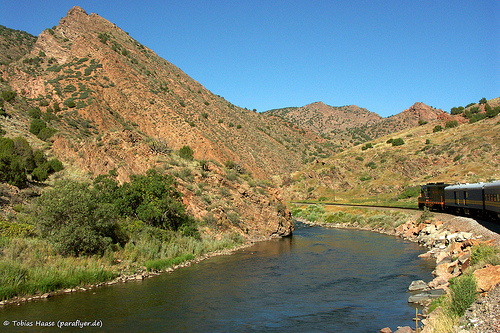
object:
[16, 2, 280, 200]
hill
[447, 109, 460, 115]
bushes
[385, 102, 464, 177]
hill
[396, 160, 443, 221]
ground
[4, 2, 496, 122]
sky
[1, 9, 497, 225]
hills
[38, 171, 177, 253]
bush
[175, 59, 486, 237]
valley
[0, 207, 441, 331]
river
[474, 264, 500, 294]
stones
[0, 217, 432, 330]
water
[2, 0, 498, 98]
sky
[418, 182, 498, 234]
railway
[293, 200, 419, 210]
line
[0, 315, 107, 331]
copyright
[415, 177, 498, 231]
train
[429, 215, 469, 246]
land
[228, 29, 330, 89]
blue sky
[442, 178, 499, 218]
passenger cars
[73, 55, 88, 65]
tree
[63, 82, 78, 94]
tree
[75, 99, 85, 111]
tree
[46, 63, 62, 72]
tree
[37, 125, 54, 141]
tree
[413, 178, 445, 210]
engine